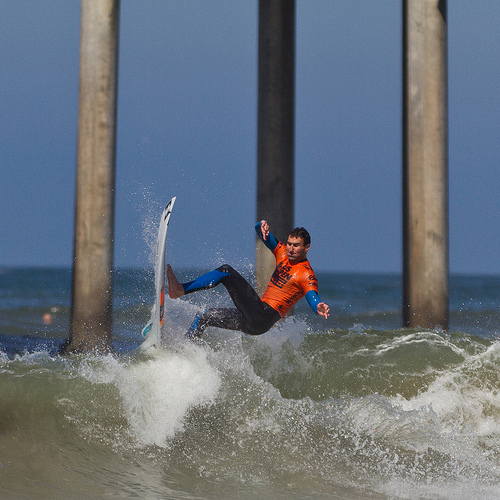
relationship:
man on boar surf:
[166, 218, 331, 349] [141, 306, 275, 452]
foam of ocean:
[109, 357, 187, 430] [11, 263, 493, 485]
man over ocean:
[166, 218, 331, 349] [0, 268, 500, 498]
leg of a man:
[166, 264, 262, 313] [166, 217, 331, 334]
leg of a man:
[183, 306, 242, 340] [166, 217, 331, 334]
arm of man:
[299, 267, 334, 324] [166, 218, 331, 349]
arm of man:
[246, 212, 293, 259] [166, 218, 331, 349]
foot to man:
[162, 261, 185, 298] [155, 208, 341, 357]